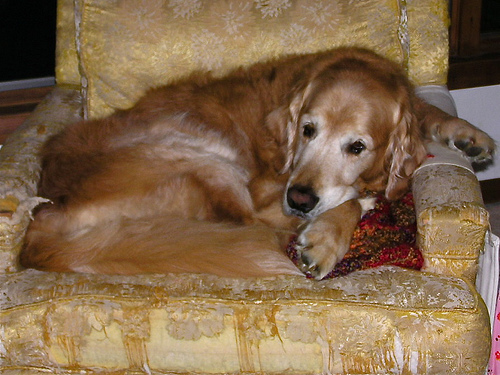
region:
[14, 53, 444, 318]
a dog in the chair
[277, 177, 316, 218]
the nose is brown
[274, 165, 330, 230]
the nose is brown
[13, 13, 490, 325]
an old golden retriever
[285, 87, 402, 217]
a dog with a graying muzzle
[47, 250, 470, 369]
the worn in cushion of an arm chair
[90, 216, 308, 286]
the fluffy tail of a dog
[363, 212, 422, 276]
a red blanket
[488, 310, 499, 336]
a pink bag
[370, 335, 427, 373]
a tear in the chair cushion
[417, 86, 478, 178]
a white piece of fabric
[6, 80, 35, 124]
a wooden table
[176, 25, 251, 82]
flowered upholstery fabric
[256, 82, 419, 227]
head of a dog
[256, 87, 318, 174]
ear of a dog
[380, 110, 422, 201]
ear of a dog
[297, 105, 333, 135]
eye of a dog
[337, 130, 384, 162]
eye of a dog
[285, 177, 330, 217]
nose of a dog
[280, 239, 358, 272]
paw of a dog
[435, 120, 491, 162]
paw of a dog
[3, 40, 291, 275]
body of a dog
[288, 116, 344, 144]
an eye of a dog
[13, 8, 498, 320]
A dog seated on an arm chair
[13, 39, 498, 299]
A dog seated on an arm chair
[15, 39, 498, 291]
A dog seated on an arm chair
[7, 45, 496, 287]
A dog seated on an arm chair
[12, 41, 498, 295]
A dog seated on an arm chair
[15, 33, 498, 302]
A dog seated on an arm chair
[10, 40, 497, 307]
A dog seated on an arm chair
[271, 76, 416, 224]
head of a dog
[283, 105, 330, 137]
eye of a dog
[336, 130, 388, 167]
eye of a dog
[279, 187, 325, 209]
nose of a dog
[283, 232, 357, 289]
paw of a dog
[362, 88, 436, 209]
ear of a dog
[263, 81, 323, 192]
ear of a dog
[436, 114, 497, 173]
paw of a dog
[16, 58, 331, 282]
body of a dog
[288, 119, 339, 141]
an eye of a dog